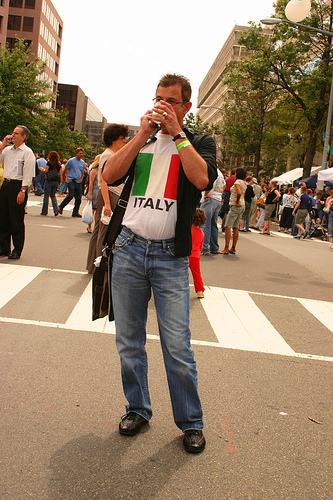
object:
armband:
[176, 139, 193, 152]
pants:
[188, 256, 205, 293]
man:
[101, 70, 220, 457]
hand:
[151, 99, 179, 136]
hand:
[140, 108, 159, 135]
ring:
[162, 112, 168, 118]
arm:
[20, 146, 35, 193]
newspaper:
[17, 159, 25, 176]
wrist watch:
[171, 131, 186, 142]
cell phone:
[7, 136, 13, 141]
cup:
[152, 100, 165, 125]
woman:
[219, 167, 248, 255]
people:
[291, 185, 310, 240]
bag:
[91, 151, 140, 325]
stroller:
[304, 188, 316, 233]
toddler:
[188, 207, 207, 299]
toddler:
[147, 118, 208, 227]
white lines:
[295, 353, 333, 363]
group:
[0, 70, 332, 456]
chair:
[306, 206, 330, 243]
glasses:
[152, 95, 184, 107]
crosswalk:
[0, 262, 333, 362]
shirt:
[120, 128, 186, 243]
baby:
[315, 217, 325, 235]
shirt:
[188, 226, 204, 259]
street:
[0, 191, 332, 500]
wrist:
[170, 126, 187, 143]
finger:
[151, 107, 169, 118]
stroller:
[320, 185, 333, 241]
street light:
[258, 15, 333, 167]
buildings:
[195, 20, 277, 181]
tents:
[317, 165, 333, 181]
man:
[0, 123, 36, 261]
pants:
[0, 176, 29, 254]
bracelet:
[176, 139, 191, 151]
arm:
[174, 132, 218, 192]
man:
[57, 147, 85, 219]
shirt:
[65, 156, 86, 184]